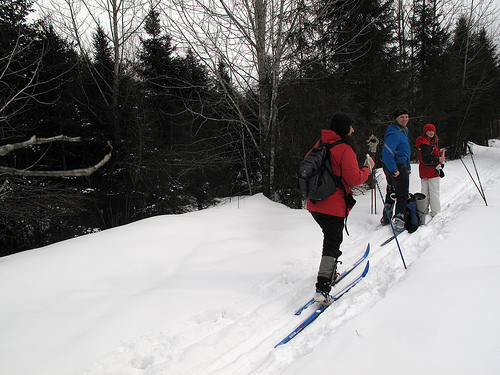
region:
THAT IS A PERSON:
[305, 118, 369, 313]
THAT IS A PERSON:
[384, 105, 416, 210]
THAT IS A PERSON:
[403, 126, 446, 225]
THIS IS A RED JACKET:
[337, 154, 358, 191]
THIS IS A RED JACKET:
[420, 143, 441, 175]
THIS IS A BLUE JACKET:
[386, 128, 404, 171]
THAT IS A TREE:
[250, 58, 277, 181]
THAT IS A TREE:
[109, 10, 131, 140]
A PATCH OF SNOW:
[367, 275, 388, 327]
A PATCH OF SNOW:
[179, 245, 264, 329]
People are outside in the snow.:
[0, 0, 496, 368]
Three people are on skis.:
[271, 85, 487, 350]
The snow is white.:
[20, 277, 230, 368]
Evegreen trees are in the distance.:
[0, 0, 280, 250]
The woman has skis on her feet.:
[260, 227, 380, 350]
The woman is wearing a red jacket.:
[301, 126, 371, 216]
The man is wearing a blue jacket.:
[381, 120, 411, 172]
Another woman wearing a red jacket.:
[413, 136, 443, 176]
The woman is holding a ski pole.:
[365, 151, 410, 276]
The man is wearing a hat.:
[392, 105, 411, 123]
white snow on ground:
[16, 279, 53, 314]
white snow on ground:
[107, 265, 132, 287]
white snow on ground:
[186, 236, 208, 253]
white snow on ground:
[269, 226, 290, 250]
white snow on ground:
[89, 346, 145, 357]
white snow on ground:
[191, 285, 237, 322]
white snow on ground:
[327, 343, 355, 363]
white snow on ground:
[414, 266, 445, 277]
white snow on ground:
[431, 335, 453, 348]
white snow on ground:
[465, 170, 490, 182]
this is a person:
[305, 111, 367, 296]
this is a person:
[384, 105, 424, 210]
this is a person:
[420, 118, 454, 228]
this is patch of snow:
[205, 268, 241, 313]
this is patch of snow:
[87, 290, 142, 328]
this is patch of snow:
[379, 263, 433, 323]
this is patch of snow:
[207, 208, 247, 265]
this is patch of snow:
[449, 161, 476, 229]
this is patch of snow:
[331, 310, 372, 329]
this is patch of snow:
[136, 260, 208, 338]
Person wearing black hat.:
[326, 114, 368, 154]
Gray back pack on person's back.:
[302, 150, 348, 217]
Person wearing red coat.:
[296, 143, 370, 220]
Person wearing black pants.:
[310, 210, 351, 255]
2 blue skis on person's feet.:
[283, 261, 351, 324]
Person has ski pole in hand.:
[346, 168, 458, 285]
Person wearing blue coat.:
[381, 122, 424, 170]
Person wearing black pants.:
[388, 161, 420, 214]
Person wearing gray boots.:
[388, 203, 428, 261]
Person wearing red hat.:
[416, 116, 451, 150]